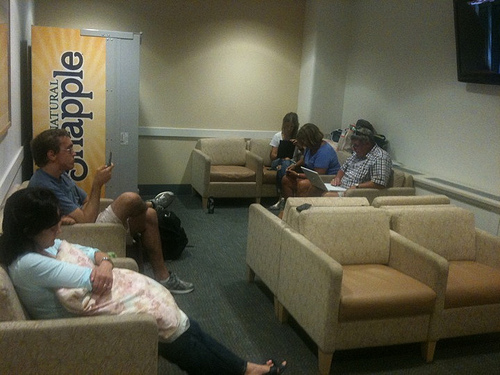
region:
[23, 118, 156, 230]
man in blue shirt on cell phone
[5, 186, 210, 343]
woman in blue shirt holding pillow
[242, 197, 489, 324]
brown chairs in a waiting room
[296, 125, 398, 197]
man in button down shirt on laptop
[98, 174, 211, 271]
black packpack on floor next to man in blue shirt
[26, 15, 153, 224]
vending machine in waiting room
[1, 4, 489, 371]
people waiting in a room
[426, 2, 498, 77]
tv on the wall of a waiting room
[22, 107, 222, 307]
man on cell phone with legs crossed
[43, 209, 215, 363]
pink pillowcase being held by woman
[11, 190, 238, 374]
woman with a pillow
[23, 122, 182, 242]
man in blue shirt looking at phone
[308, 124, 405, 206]
man in plaid shirt looking at laptop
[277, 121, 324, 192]
woman in blue shirt looking at phone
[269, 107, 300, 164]
woman in white shirt looking at tablet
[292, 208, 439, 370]
tan arm chair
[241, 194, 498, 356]
group of four arm chairs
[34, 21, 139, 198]
snapple vending machine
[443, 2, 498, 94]
wall mounted flatscreen tv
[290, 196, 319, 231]
black tv remote control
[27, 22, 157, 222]
Snapple cold beverage case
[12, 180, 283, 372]
woman holding a pillow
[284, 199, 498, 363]
pair of empty chairs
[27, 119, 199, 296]
man looking at his phone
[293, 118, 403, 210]
man using his laptop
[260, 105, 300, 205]
woman using a tablet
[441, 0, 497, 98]
TV mounted to the wall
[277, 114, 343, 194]
woman wearing a blue shirt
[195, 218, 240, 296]
greenish gray carpeting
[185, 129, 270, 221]
brown and tan chair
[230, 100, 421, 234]
three people sitting on armchairs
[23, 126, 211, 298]
young man looking at his phone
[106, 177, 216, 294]
one leg resting on the other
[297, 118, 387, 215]
man on his laptop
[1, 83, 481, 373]
five people in a waiting room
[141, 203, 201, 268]
black backpack on the ground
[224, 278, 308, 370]
shadow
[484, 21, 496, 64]
reflection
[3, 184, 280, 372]
a woman sitting in chair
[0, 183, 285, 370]
a woman holding pink pillow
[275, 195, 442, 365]
an empty tan chair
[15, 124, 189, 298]
a man sitting in chair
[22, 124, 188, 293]
a man texting on cellphone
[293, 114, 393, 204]
a man using a laptop computer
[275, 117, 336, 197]
a woman looking down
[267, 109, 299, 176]
a girl reading a book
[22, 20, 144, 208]
a large vending machine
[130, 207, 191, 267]
a black backpack on floor